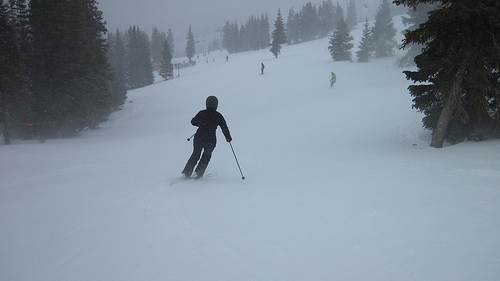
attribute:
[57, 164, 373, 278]
ground — covered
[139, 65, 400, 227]
snow — white, thick, pure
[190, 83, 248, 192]
skier — female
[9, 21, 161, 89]
area — forest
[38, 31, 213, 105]
trees — evergreen, growing, tipping, big